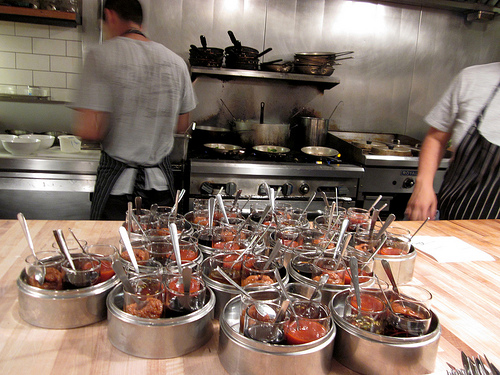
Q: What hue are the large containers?
A: Silver.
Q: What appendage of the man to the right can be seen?
A: Right arm and hand.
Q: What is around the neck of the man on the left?
A: Black apron string.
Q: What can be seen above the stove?
A: Four piles of pans.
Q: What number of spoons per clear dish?
A: One.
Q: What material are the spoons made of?
A: Medal.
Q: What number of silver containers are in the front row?
A: Two.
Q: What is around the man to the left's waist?
A: An apron.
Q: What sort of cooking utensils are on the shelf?
A: Pans.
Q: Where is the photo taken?
A: In a kitchen.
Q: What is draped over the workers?
A: Aprons.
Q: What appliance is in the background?
A: An oven.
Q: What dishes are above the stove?
A: Black pans.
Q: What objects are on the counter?
A: Stainless steel pots.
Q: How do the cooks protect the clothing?
A: With aprons.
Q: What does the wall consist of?
A: Stainless steel.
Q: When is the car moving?
A: There is no car.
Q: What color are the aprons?
A: Black and white.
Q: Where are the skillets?
A: On the shelf.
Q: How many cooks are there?
A: Two.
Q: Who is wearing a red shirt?
A: No one.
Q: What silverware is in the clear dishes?
A: Spoons.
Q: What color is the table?
A: Brown.